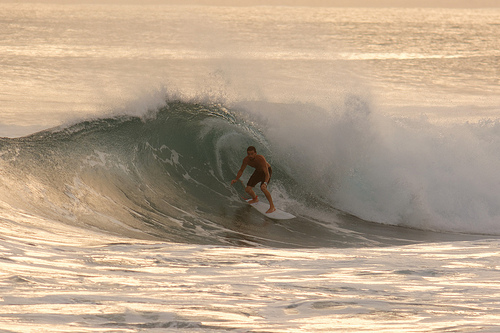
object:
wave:
[0, 88, 499, 246]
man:
[229, 143, 277, 213]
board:
[242, 194, 298, 222]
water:
[0, 2, 499, 333]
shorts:
[247, 166, 272, 188]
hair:
[246, 145, 256, 153]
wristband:
[262, 180, 268, 185]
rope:
[252, 194, 258, 201]